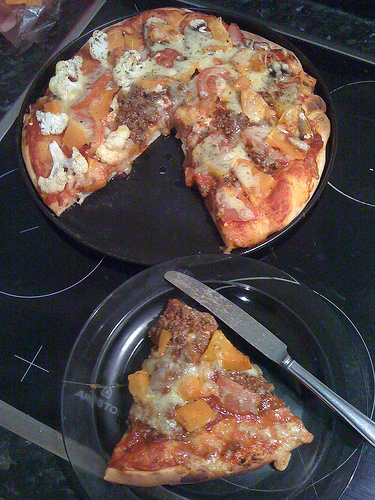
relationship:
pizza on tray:
[19, 7, 330, 248] [17, 7, 337, 270]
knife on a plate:
[163, 268, 374, 448] [59, 253, 374, 496]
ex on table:
[14, 345, 48, 382] [2, 3, 366, 499]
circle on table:
[1, 168, 108, 300] [2, 3, 366, 499]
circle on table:
[329, 77, 374, 212] [2, 3, 366, 499]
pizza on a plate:
[103, 299, 312, 481] [59, 253, 374, 496]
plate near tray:
[59, 253, 374, 496] [17, 7, 337, 270]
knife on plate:
[163, 268, 374, 448] [59, 253, 374, 496]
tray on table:
[17, 7, 337, 270] [2, 3, 366, 499]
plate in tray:
[59, 253, 374, 496] [17, 7, 337, 270]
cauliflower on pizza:
[98, 124, 134, 164] [19, 7, 330, 248]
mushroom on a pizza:
[191, 19, 207, 37] [19, 7, 330, 248]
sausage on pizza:
[119, 82, 158, 139] [19, 7, 330, 248]